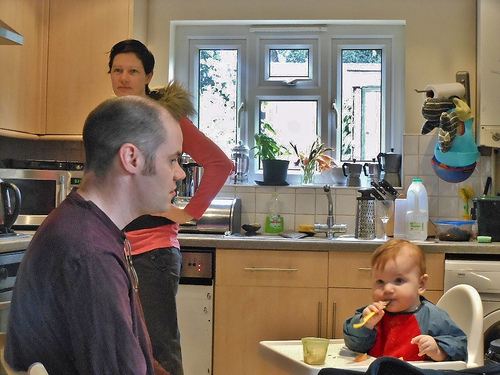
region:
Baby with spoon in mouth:
[377, 258, 420, 316]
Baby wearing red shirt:
[348, 294, 454, 349]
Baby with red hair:
[355, 238, 421, 281]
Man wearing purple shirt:
[26, 187, 159, 361]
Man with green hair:
[149, 85, 196, 120]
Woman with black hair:
[99, 38, 156, 69]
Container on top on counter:
[399, 177, 440, 244]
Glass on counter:
[366, 197, 396, 238]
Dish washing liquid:
[265, 190, 289, 239]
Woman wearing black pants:
[134, 225, 201, 371]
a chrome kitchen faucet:
[307, 181, 347, 240]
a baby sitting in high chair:
[263, 239, 485, 364]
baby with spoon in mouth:
[337, 239, 463, 360]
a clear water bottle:
[405, 176, 430, 241]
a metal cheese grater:
[350, 186, 376, 241]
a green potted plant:
[252, 117, 290, 189]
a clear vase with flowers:
[287, 137, 333, 184]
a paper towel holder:
[413, 80, 465, 102]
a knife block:
[363, 177, 440, 240]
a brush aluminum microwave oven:
[0, 168, 91, 227]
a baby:
[345, 214, 459, 355]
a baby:
[388, 282, 437, 357]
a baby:
[386, 258, 416, 372]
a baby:
[356, 252, 427, 362]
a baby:
[392, 228, 486, 371]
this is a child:
[345, 235, 447, 353]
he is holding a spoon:
[360, 296, 389, 329]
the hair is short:
[373, 242, 400, 261]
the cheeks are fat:
[400, 289, 414, 299]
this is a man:
[27, 95, 192, 370]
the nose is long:
[175, 168, 184, 178]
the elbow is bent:
[197, 150, 229, 182]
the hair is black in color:
[120, 37, 140, 51]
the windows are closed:
[209, 55, 375, 131]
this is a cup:
[302, 337, 332, 362]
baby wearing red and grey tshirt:
[349, 228, 475, 370]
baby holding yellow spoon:
[343, 231, 472, 373]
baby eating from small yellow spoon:
[333, 242, 475, 367]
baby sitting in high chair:
[260, 215, 497, 372]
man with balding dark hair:
[21, 93, 199, 373]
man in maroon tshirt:
[9, 90, 194, 374]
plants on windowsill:
[251, 119, 340, 190]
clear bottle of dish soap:
[261, 189, 288, 239]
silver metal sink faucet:
[316, 183, 347, 243]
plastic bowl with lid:
[433, 216, 478, 248]